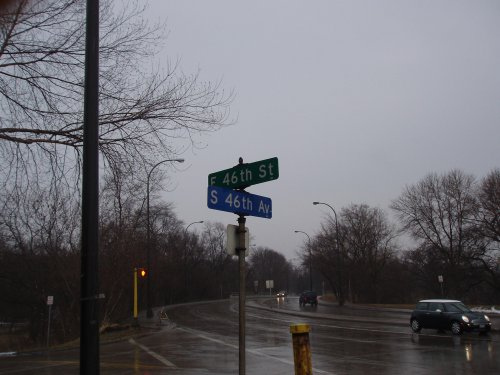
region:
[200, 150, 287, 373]
two street signs on metal pole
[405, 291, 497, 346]
black and white two door car on wet road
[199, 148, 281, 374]
street sign on side of road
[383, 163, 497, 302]
tall leafless brown tree behind black and white car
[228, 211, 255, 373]
metal traffic sign support pole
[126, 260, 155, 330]
short red traffic light on side of street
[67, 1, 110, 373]
brown pole behind street sign pole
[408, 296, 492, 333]
a small blue and white vehicle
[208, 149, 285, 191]
a green and white street sign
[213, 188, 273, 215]
a blue and white street sign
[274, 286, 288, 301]
a vehicle with the headlights on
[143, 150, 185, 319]
a tall street light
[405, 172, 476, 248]
trees with no leaves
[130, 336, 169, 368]
a white line painted on a street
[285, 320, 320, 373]
a yellow rusted post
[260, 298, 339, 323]
a concret medium in the road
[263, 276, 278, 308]
a traffic sign on a street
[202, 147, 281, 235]
green and blue street signs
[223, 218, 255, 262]
back of white sign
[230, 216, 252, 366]
metal pole with signs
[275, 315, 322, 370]
dirty yellow pipe by signs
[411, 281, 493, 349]
black mini cooper with white roof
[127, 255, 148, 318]
illuminated street lamp on yellow pole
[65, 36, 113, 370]
tall dark pole to left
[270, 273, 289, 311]
headlights of oncoming car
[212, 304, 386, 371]
wet shining street behind sign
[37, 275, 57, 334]
white sign on pole to left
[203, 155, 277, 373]
street sign on metal pole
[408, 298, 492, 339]
car is mini cooper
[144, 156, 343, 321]
metal lamp posts with street lights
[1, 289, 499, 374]
black paved wet road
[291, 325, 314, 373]
yellow pole by street sign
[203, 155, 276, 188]
green sign says E 46th St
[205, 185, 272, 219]
blue sign says S 46th Av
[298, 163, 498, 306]
group of trees on right of road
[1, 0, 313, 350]
trees on left side of road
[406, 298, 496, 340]
black vehicle with a white roof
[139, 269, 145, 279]
orange colored light on a pole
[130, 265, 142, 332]
tall yellow pole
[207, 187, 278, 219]
blue and white street sign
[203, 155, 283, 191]
green and white colored street sign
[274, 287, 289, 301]
car in the distance with lights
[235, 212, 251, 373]
metal post for street signs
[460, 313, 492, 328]
headlights on a dark vehicle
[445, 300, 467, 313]
windshield on a black vehicle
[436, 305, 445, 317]
rear view mirror on a black vehicle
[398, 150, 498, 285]
The trees have no leaves.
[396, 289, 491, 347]
A mini cooper is on the road.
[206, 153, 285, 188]
A sign that say E 46th St.